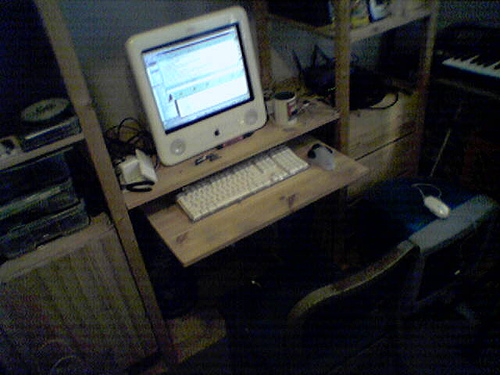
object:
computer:
[120, 3, 271, 167]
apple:
[212, 128, 222, 141]